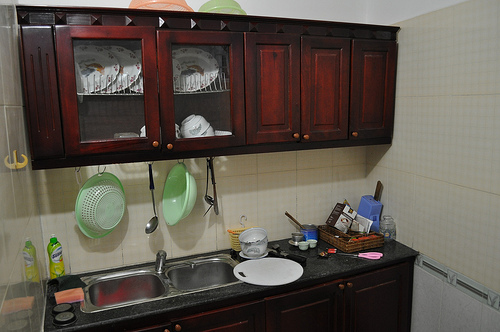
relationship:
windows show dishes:
[71, 37, 235, 145] [75, 44, 220, 91]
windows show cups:
[71, 37, 235, 145] [141, 114, 231, 139]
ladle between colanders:
[144, 164, 160, 235] [75, 162, 198, 239]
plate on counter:
[233, 257, 304, 286] [43, 237, 420, 331]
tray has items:
[320, 225, 385, 251] [318, 199, 381, 240]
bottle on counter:
[46, 236, 66, 280] [43, 237, 420, 331]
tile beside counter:
[415, 253, 499, 313] [43, 237, 420, 331]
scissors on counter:
[336, 249, 383, 261] [43, 237, 420, 331]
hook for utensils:
[13, 150, 29, 172] [75, 158, 220, 241]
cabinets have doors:
[16, 5, 401, 171] [54, 25, 245, 155]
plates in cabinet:
[75, 44, 220, 91] [16, 5, 401, 171]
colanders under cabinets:
[75, 162, 198, 239] [16, 5, 401, 171]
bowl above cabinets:
[129, 0, 194, 10] [16, 5, 401, 171]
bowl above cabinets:
[199, 0, 247, 17] [16, 5, 401, 171]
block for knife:
[357, 195, 384, 234] [373, 181, 383, 201]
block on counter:
[357, 195, 384, 234] [43, 237, 420, 331]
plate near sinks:
[233, 257, 304, 286] [80, 248, 244, 314]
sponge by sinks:
[54, 287, 86, 307] [80, 248, 244, 314]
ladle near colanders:
[144, 164, 160, 235] [75, 162, 198, 239]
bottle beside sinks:
[46, 236, 66, 280] [80, 248, 244, 314]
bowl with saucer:
[239, 227, 268, 256] [237, 251, 270, 258]